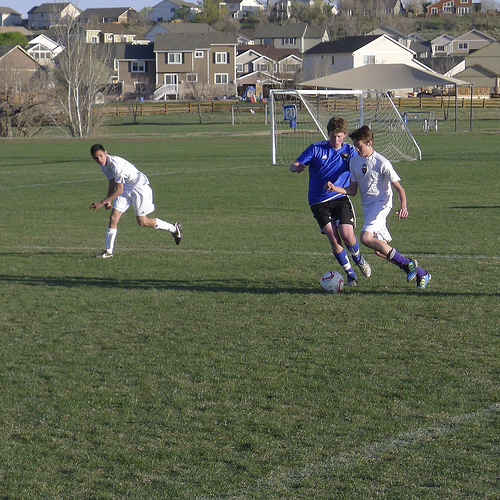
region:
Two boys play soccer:
[276, 106, 439, 298]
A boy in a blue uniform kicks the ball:
[288, 118, 376, 295]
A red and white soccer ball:
[320, 270, 350, 299]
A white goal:
[268, 88, 427, 166]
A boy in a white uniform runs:
[83, 141, 190, 260]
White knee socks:
[96, 228, 121, 260]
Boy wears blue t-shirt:
[288, 138, 356, 210]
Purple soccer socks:
[387, 241, 412, 270]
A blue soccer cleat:
[419, 271, 434, 291]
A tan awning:
[296, 64, 468, 90]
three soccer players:
[75, 115, 436, 296]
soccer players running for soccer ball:
[281, 109, 448, 306]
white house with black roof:
[293, 24, 421, 92]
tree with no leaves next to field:
[38, 25, 106, 135]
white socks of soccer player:
[101, 218, 185, 254]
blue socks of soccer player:
[331, 237, 363, 270]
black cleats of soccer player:
[93, 220, 184, 265]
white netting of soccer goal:
[267, 79, 416, 165]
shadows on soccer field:
[19, 252, 498, 328]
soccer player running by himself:
[73, 140, 185, 255]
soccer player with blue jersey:
[288, 117, 365, 283]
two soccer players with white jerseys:
[75, 127, 433, 277]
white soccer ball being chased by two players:
[311, 272, 347, 293]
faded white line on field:
[228, 393, 494, 497]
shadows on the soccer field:
[10, 192, 478, 324]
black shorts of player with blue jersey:
[313, 192, 355, 230]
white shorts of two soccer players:
[105, 183, 397, 238]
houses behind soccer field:
[1, 5, 491, 84]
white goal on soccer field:
[265, 83, 423, 163]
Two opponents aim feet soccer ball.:
[286, 115, 457, 305]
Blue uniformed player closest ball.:
[290, 115, 365, 298]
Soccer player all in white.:
[73, 134, 212, 269]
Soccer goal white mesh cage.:
[256, 81, 443, 171]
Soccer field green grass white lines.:
[5, 129, 487, 483]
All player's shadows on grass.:
[7, 237, 499, 314]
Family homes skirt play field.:
[115, 6, 486, 79]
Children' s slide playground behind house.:
[245, 85, 267, 108]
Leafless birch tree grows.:
[32, 17, 112, 137]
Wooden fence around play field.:
[399, 95, 499, 111]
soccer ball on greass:
[315, 262, 346, 300]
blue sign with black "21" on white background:
[281, 101, 298, 131]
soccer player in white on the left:
[75, 141, 185, 261]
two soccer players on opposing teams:
[289, 107, 445, 292]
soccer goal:
[266, 83, 431, 170]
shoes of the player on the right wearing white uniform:
[395, 262, 435, 289]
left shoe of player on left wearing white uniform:
[168, 216, 186, 249]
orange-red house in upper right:
[415, 0, 474, 25]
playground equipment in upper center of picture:
[238, 83, 268, 110]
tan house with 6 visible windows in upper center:
[152, 26, 238, 104]